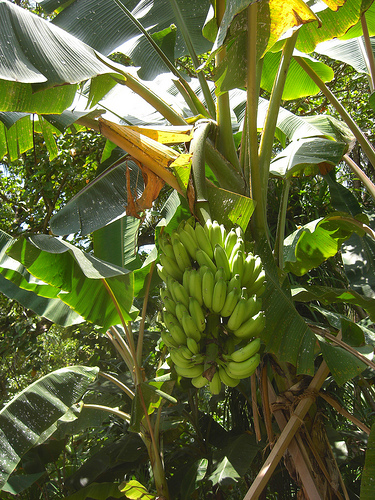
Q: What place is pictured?
A: It is a field.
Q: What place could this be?
A: It is a field.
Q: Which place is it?
A: It is a field.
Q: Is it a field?
A: Yes, it is a field.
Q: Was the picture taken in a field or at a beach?
A: It was taken at a field.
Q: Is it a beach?
A: No, it is a field.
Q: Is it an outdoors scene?
A: Yes, it is outdoors.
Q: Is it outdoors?
A: Yes, it is outdoors.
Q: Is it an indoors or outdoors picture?
A: It is outdoors.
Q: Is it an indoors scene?
A: No, it is outdoors.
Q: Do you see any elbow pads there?
A: No, there are no elbow pads.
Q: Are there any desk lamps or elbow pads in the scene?
A: No, there are no elbow pads or desk lamps.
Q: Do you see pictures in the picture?
A: No, there are no pictures.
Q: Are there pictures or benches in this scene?
A: No, there are no pictures or benches.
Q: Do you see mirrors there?
A: No, there are no mirrors.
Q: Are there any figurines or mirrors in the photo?
A: No, there are no mirrors or figurines.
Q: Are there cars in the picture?
A: No, there are no cars.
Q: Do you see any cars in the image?
A: No, there are no cars.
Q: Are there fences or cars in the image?
A: No, there are no cars or fences.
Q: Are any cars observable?
A: No, there are no cars.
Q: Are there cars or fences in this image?
A: No, there are no cars or fences.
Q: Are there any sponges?
A: No, there are no sponges.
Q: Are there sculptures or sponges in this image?
A: No, there are no sponges or sculptures.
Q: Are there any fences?
A: No, there are no fences.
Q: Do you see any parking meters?
A: No, there are no parking meters.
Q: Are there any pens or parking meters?
A: No, there are no parking meters or pens.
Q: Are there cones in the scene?
A: No, there are no cones.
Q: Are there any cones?
A: No, there are no cones.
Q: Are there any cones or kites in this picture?
A: No, there are no cones or kites.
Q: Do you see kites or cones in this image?
A: No, there are no cones or kites.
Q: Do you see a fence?
A: No, there are no fences.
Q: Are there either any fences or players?
A: No, there are no fences or players.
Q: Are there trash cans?
A: No, there are no trash cans.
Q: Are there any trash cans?
A: No, there are no trash cans.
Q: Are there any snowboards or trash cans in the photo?
A: No, there are no trash cans or snowboards.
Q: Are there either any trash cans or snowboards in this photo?
A: No, there are no trash cans or snowboards.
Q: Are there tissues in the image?
A: No, there are no tissues.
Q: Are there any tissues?
A: No, there are no tissues.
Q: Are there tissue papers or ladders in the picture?
A: No, there are no tissue papers or ladders.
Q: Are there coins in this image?
A: No, there are no coins.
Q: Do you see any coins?
A: No, there are no coins.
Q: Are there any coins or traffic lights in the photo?
A: No, there are no coins or traffic lights.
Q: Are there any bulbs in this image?
A: No, there are no bulbs.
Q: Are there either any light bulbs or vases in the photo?
A: No, there are no light bulbs or vases.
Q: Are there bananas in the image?
A: Yes, there is a banana.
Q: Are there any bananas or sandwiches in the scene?
A: Yes, there is a banana.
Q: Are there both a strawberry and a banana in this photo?
A: No, there is a banana but no strawberries.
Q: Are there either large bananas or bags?
A: Yes, there is a large banana.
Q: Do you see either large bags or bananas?
A: Yes, there is a large banana.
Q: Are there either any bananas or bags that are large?
A: Yes, the banana is large.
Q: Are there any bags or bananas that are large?
A: Yes, the banana is large.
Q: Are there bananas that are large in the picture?
A: Yes, there is a large banana.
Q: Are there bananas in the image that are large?
A: Yes, there is a banana that is large.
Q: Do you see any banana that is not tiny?
A: Yes, there is a large banana.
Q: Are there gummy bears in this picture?
A: No, there are no gummy bears.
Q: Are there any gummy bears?
A: No, there are no gummy bears.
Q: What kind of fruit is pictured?
A: The fruit is a banana.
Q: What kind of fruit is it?
A: The fruit is a banana.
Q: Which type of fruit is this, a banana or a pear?
A: That is a banana.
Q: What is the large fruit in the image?
A: The fruit is a banana.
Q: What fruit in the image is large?
A: The fruit is a banana.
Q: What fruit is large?
A: The fruit is a banana.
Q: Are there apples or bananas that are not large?
A: No, there is a banana but it is large.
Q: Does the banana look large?
A: Yes, the banana is large.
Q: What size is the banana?
A: The banana is large.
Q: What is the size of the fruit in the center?
A: The banana is large.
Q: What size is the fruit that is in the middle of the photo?
A: The banana is large.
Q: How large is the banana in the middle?
A: The banana is large.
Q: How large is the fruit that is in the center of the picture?
A: The banana is large.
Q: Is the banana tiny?
A: No, the banana is large.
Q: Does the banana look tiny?
A: No, the banana is large.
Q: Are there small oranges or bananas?
A: No, there is a banana but it is large.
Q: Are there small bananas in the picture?
A: No, there is a banana but it is large.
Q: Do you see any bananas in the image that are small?
A: No, there is a banana but it is large.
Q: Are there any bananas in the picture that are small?
A: No, there is a banana but it is large.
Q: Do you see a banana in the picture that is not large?
A: No, there is a banana but it is large.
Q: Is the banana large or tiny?
A: The banana is large.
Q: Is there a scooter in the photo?
A: No, there are no scooters.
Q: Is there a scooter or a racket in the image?
A: No, there are no scooters or rackets.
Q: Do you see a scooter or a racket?
A: No, there are no scooters or rackets.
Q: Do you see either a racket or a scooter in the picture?
A: No, there are no scooters or rackets.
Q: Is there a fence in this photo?
A: No, there are no fences.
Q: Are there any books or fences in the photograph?
A: No, there are no fences or books.